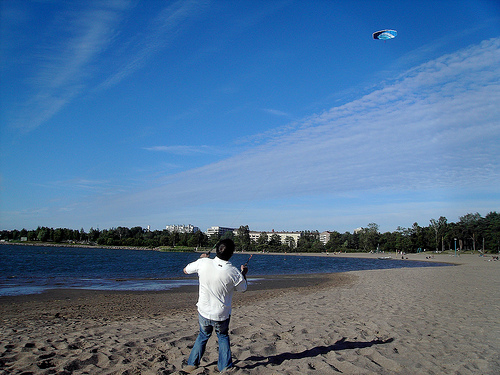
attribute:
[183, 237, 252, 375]
person — man, standing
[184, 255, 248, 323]
shirt — white, polo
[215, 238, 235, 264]
hair — dark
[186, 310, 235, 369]
jeans — blue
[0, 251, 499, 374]
sand — trampled, light brown, footprinted, wet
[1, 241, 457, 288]
water — blue, beautiful, calm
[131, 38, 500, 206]
clouds — white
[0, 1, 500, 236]
sky — bright blue, blue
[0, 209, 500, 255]
trees — green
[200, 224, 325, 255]
building — large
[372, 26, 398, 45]
kite — airborn, blue